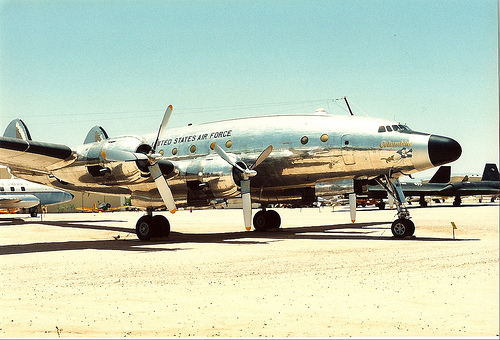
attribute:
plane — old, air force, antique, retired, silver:
[0, 103, 462, 240]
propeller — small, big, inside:
[208, 140, 276, 236]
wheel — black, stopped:
[388, 215, 415, 239]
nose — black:
[398, 128, 462, 173]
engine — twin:
[128, 141, 251, 203]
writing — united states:
[152, 128, 236, 149]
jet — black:
[365, 162, 499, 208]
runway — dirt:
[1, 199, 499, 338]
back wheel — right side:
[134, 216, 161, 244]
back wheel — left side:
[252, 208, 276, 235]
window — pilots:
[376, 125, 389, 137]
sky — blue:
[2, 1, 500, 180]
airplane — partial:
[1, 165, 77, 221]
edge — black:
[1, 136, 76, 164]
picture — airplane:
[2, 0, 500, 340]